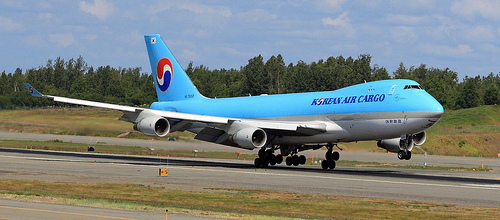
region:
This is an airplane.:
[78, 22, 449, 170]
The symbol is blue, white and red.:
[134, 43, 211, 101]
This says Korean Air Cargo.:
[308, 74, 412, 125]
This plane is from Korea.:
[283, 88, 356, 119]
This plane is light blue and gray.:
[24, 13, 435, 162]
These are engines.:
[123, 106, 285, 150]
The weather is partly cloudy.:
[46, 3, 458, 60]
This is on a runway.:
[31, 52, 494, 215]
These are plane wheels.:
[253, 150, 359, 180]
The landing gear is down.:
[221, 136, 367, 200]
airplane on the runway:
[21, 18, 451, 187]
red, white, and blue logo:
[151, 54, 180, 94]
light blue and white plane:
[11, 23, 469, 184]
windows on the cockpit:
[403, 79, 428, 94]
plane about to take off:
[8, 18, 473, 183]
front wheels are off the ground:
[399, 131, 416, 166]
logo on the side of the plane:
[301, 86, 388, 114]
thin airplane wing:
[10, 80, 310, 158]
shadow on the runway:
[7, 141, 499, 192]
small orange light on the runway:
[153, 164, 173, 181]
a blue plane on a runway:
[92, 36, 458, 164]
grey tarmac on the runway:
[311, 178, 416, 192]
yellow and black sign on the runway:
[147, 152, 174, 180]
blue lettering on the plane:
[321, 93, 395, 109]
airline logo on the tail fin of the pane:
[137, 60, 180, 93]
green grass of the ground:
[211, 193, 287, 211]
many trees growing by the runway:
[18, 63, 407, 90]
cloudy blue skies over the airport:
[160, 0, 427, 46]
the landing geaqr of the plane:
[248, 145, 342, 184]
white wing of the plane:
[55, 89, 277, 157]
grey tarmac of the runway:
[367, 171, 464, 199]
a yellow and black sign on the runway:
[152, 155, 174, 177]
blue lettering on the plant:
[317, 91, 389, 107]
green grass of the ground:
[155, 195, 327, 212]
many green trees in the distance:
[16, 62, 371, 88]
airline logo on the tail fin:
[148, 54, 179, 94]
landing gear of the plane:
[245, 143, 356, 178]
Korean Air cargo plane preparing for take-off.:
[23, 33, 444, 169]